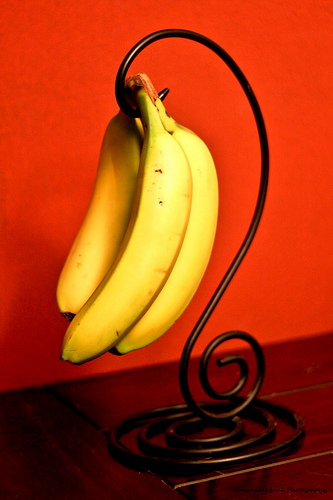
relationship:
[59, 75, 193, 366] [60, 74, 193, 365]
banana has brown spots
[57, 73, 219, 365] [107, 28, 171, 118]
bananas on hook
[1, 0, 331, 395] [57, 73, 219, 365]
wall behind bananas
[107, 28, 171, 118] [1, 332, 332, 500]
hook on table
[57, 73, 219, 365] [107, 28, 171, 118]
bananas on a hook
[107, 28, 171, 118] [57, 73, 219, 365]
hook holding bananas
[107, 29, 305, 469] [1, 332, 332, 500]
banana stand on table